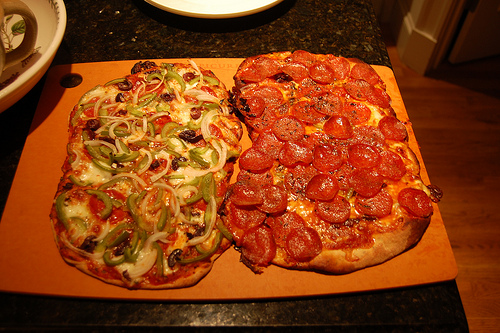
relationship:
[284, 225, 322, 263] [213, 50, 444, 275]
pepperoni slice on top of pizza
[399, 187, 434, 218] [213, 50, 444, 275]
pepperoni slice on top of pizza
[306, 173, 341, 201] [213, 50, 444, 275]
pepperoni slice on top of pizza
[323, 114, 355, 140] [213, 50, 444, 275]
pepperoni slice on top of pizza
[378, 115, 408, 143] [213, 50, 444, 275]
pepperoni slice on top of pizza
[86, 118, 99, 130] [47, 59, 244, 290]
olive on top of pizza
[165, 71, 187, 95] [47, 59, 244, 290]
green pepper on top of pizza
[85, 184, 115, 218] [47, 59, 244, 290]
green pepper on top of pizza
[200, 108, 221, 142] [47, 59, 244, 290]
onion slice on top of pizza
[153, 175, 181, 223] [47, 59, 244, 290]
onion slice on top of pizza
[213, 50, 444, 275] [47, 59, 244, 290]
pizza next to pizza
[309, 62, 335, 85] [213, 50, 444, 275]
pepperoni slice on top of pizza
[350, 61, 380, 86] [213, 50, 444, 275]
pepperoni slice on top of pizza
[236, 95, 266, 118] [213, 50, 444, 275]
pepperoni slice on top of pizza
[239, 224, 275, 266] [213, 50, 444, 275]
pepperoni slice on top of pizza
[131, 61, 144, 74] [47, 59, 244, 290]
black olive on top of pizza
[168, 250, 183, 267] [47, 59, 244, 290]
black olive on top of pizza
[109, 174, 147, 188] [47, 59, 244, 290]
onion slice on top of pizza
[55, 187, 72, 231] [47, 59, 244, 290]
green pepper on top of pizza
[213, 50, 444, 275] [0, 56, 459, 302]
pizza on top of tray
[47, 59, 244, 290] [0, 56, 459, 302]
pizza on top of tray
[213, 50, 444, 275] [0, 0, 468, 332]
pizza on top of counter top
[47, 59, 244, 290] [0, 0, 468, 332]
pizza on top of counter top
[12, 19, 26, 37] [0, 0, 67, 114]
foliage painted in bowl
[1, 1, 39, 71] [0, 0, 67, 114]
cup inside bowl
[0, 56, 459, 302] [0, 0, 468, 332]
tray on top of counter top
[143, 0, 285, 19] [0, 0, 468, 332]
plate on top of counter top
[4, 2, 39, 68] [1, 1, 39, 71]
handle attached to cup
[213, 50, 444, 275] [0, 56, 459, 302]
pizza resting on tray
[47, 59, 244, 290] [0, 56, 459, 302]
pizza resting on tray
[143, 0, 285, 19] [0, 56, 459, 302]
plate above tray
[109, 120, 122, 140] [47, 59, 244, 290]
onion slice on top of pizza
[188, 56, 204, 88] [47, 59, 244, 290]
onion slice on top of pizza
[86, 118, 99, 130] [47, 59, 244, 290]
black olive on top of pizza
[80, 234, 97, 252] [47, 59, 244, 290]
black olive on top of pizza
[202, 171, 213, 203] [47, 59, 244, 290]
green pepper on top of pizza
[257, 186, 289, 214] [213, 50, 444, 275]
pepperoni slice on top of pizza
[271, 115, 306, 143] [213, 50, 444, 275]
pepperoni slice on top of pizza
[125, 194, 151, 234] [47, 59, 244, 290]
green pepper on top of pizza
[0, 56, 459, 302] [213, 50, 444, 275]
tray holding pizza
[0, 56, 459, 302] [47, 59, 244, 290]
tray holding pizza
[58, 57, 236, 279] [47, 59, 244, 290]
toppings on top of pizza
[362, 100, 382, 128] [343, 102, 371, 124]
cheese below pepperoni slice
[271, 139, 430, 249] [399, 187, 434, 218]
cheese below pepperoni slice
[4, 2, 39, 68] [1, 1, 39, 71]
handle attaced to cup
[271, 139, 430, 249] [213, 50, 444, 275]
cheese on top of pizza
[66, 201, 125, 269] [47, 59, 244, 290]
cheese on top of pizza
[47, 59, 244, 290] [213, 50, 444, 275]
pizza next to pizza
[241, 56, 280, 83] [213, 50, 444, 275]
pepperoni slice on top of pizza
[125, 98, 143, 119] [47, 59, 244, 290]
green pepper on top of pizza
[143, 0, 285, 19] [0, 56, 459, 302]
plate near tray